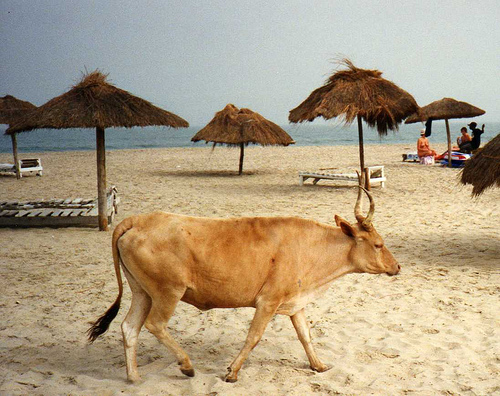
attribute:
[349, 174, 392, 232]
horns — pointy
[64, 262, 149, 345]
tail — black, bushy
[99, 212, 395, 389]
cow — brown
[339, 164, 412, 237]
horns — pointy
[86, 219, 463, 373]
cow — walking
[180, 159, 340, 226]
sand — yellow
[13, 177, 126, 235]
chairs — white, lounge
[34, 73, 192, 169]
umbrella — brown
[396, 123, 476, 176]
people — sitting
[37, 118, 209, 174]
water — blue, clear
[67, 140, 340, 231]
beach — sandy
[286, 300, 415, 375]
sand — light brown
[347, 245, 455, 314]
nose — brown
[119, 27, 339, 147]
sky — white, grey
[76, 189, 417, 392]
cow — white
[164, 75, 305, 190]
water — grey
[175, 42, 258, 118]
sky — hazy